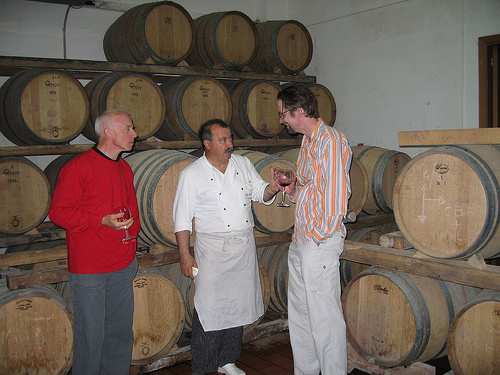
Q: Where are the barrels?
A: On planks.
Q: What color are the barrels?
A: Brown and gray.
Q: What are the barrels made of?
A: Wood and metal.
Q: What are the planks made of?
A: Wood.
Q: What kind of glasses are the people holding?
A: Wine glasses.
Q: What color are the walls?
A: White.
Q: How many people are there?
A: Three.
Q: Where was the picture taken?
A: In a winery.